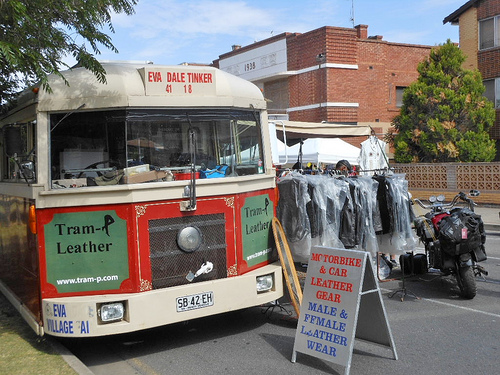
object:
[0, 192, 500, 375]
road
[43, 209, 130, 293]
advertisments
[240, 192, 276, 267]
advertisments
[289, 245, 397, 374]
advertisments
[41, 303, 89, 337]
print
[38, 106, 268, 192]
front window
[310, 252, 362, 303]
print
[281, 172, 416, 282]
plastic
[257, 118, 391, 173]
vendor tents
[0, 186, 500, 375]
ground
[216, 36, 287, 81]
white sign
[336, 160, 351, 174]
head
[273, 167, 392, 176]
rack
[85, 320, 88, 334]
blue letter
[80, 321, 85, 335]
blue letter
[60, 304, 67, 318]
blue letter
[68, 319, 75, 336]
blue letter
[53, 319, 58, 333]
blue letter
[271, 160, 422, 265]
clothes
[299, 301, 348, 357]
blue text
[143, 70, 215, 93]
text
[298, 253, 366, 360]
text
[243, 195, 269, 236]
text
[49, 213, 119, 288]
text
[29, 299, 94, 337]
text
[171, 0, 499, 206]
building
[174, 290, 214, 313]
license plate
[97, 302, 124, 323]
headlight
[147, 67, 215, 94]
sign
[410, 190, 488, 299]
motorcycle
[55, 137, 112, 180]
driver seat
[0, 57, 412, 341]
store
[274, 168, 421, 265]
bags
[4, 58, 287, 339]
bus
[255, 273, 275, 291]
light